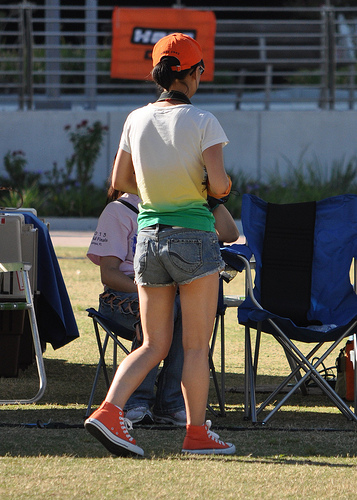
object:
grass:
[136, 455, 345, 499]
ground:
[4, 404, 344, 481]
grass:
[10, 457, 134, 486]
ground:
[2, 181, 344, 495]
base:
[243, 330, 346, 416]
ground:
[0, 450, 355, 499]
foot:
[82, 408, 145, 458]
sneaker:
[125, 405, 154, 423]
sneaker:
[154, 408, 187, 425]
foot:
[126, 404, 155, 429]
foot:
[157, 406, 188, 426]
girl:
[82, 35, 238, 461]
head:
[148, 30, 203, 96]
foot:
[178, 436, 235, 453]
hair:
[150, 54, 207, 89]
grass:
[0, 244, 356, 499]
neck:
[152, 85, 190, 107]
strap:
[154, 90, 190, 102]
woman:
[84, 174, 189, 433]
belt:
[149, 222, 176, 229]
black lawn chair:
[70, 252, 229, 397]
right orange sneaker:
[185, 412, 237, 458]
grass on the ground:
[28, 439, 110, 492]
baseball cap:
[150, 30, 206, 67]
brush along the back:
[106, 84, 207, 238]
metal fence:
[3, 5, 355, 111]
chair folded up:
[1, 204, 65, 419]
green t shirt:
[104, 108, 256, 234]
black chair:
[233, 205, 324, 341]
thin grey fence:
[6, 1, 352, 109]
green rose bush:
[55, 111, 115, 191]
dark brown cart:
[322, 331, 354, 407]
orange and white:
[117, 423, 124, 435]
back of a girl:
[110, 108, 229, 290]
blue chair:
[219, 193, 356, 421]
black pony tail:
[149, 55, 178, 93]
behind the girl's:
[89, 459, 252, 495]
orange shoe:
[82, 394, 146, 452]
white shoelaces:
[203, 418, 223, 444]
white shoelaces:
[117, 410, 135, 440]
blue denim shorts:
[134, 220, 221, 280]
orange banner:
[110, 9, 215, 79]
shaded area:
[10, 346, 353, 459]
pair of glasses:
[190, 55, 209, 80]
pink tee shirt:
[89, 185, 137, 279]